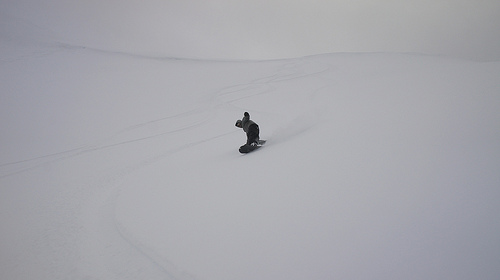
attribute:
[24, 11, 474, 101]
slope — snow covered, top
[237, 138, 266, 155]
snowboard — black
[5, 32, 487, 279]
mountain — horizon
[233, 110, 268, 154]
boy — white 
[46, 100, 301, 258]
snow — white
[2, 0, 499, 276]
snow — white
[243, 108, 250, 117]
hand — outstretched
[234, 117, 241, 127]
hair — short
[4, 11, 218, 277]
snow — white 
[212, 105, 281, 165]
arm — human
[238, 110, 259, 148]
gear — snow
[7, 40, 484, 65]
line — winding